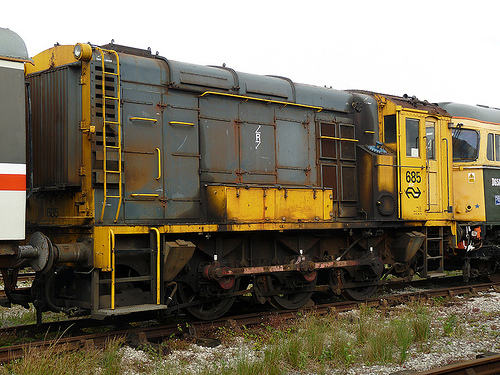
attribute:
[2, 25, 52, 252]
train car — orange, white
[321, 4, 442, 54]
sky — blue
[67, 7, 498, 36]
sky — blue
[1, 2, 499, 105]
clouds — white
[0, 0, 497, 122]
sky — blue, white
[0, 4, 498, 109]
sky — blue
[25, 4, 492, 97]
sky — blue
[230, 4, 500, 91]
clouds — white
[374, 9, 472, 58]
clouds — white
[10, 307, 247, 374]
tracks — rusted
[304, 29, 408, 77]
clouds — white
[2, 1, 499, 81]
sky — blue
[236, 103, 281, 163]
design — white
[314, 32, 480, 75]
sky — blue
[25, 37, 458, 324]
train — yellow, black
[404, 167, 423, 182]
685 — black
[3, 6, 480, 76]
sky — blue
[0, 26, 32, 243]
train — red white and gray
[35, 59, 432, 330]
train — gray, yellow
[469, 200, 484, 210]
star — blue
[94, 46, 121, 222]
ladder — yellow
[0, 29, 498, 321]
train — yellow, grey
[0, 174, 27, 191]
stripe — red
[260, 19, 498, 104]
sky — clear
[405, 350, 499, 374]
train track — cornered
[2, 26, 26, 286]
traincar — gray, white, red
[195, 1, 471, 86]
clouds — white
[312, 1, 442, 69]
clouds — white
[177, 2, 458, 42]
clouds — white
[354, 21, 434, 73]
clouds — white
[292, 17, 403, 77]
clouds — white